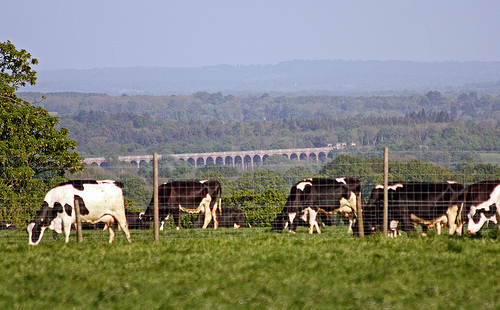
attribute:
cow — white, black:
[139, 176, 225, 235]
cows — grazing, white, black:
[26, 178, 499, 246]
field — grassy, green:
[3, 217, 498, 309]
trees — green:
[84, 157, 493, 210]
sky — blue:
[1, 0, 499, 61]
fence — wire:
[0, 161, 499, 237]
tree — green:
[0, 41, 89, 229]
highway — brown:
[76, 144, 343, 168]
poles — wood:
[146, 147, 393, 252]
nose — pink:
[466, 229, 472, 235]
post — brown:
[148, 152, 164, 241]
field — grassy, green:
[1, 226, 497, 307]